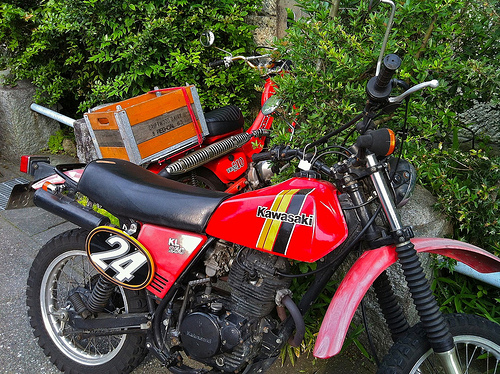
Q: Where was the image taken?
A: It was taken at the pavement.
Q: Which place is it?
A: It is a pavement.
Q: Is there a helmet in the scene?
A: No, there are no helmets.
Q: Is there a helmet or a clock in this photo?
A: No, there are no helmets or clocks.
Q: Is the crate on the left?
A: Yes, the crate is on the left of the image.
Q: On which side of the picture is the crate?
A: The crate is on the left of the image.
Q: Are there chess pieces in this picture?
A: No, there are no chess pieces.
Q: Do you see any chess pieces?
A: No, there are no chess pieces.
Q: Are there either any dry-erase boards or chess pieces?
A: No, there are no chess pieces or dry-erase boards.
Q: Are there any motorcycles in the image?
A: Yes, there is a motorcycle.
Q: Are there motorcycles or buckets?
A: Yes, there is a motorcycle.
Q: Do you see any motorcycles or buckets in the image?
A: Yes, there is a motorcycle.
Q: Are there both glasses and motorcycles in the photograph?
A: No, there is a motorcycle but no glasses.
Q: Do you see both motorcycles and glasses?
A: No, there is a motorcycle but no glasses.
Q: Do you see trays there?
A: No, there are no trays.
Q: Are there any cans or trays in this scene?
A: No, there are no trays or cans.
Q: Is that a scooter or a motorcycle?
A: That is a motorcycle.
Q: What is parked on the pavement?
A: The motorcycle is parked on the pavement.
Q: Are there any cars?
A: No, there are no cars.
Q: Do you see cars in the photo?
A: No, there are no cars.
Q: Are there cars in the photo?
A: No, there are no cars.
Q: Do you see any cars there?
A: No, there are no cars.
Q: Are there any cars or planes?
A: No, there are no cars or planes.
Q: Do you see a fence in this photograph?
A: No, there are no fences.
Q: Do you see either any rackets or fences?
A: No, there are no fences or rackets.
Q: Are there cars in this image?
A: No, there are no cars.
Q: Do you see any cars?
A: No, there are no cars.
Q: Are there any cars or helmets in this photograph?
A: No, there are no cars or helmets.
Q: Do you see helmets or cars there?
A: No, there are no cars or helmets.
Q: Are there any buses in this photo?
A: No, there are no buses.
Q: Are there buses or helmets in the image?
A: No, there are no buses or helmets.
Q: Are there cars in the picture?
A: No, there are no cars.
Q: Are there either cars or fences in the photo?
A: No, there are no cars or fences.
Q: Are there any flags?
A: No, there are no flags.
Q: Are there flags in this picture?
A: No, there are no flags.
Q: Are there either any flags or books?
A: No, there are no flags or books.